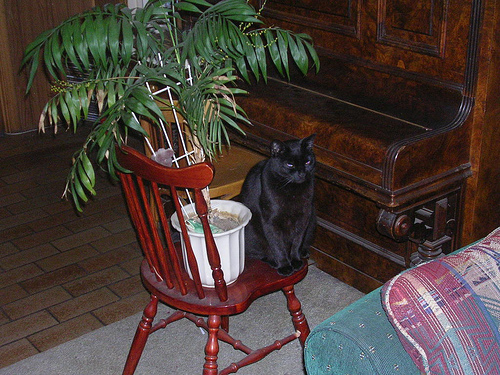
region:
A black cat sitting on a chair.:
[245, 138, 312, 273]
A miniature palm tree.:
[12, 0, 272, 145]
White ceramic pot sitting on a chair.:
[182, 195, 248, 288]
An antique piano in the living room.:
[315, 7, 499, 247]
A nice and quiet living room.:
[6, 4, 494, 374]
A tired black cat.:
[248, 134, 318, 276]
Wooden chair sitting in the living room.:
[115, 152, 300, 373]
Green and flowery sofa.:
[307, 239, 496, 373]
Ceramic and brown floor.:
[5, 180, 128, 336]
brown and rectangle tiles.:
[0, 220, 134, 317]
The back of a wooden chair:
[147, 172, 201, 287]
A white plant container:
[169, 197, 254, 287]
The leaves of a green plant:
[89, 9, 219, 92]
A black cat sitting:
[242, 133, 321, 273]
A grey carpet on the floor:
[43, 356, 123, 374]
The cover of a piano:
[321, 118, 396, 147]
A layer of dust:
[338, 228, 368, 246]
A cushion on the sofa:
[416, 287, 499, 344]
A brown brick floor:
[1, 248, 63, 329]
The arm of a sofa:
[329, 322, 386, 374]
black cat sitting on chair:
[235, 126, 320, 286]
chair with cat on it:
[114, 135, 321, 373]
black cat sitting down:
[246, 135, 323, 270]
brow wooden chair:
[93, 135, 323, 373]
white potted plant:
[170, 195, 251, 290]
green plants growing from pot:
[31, 9, 315, 227]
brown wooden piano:
[236, 0, 488, 279]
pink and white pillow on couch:
[382, 245, 499, 374]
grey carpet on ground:
[39, 323, 120, 374]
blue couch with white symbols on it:
[277, 293, 404, 374]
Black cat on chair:
[242, 138, 330, 271]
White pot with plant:
[162, 197, 256, 287]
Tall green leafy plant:
[20, 5, 308, 185]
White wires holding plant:
[127, 18, 222, 222]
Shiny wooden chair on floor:
[114, 135, 334, 373]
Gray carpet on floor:
[6, 248, 413, 369]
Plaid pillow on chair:
[382, 225, 499, 374]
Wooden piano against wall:
[147, 4, 495, 269]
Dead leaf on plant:
[93, 80, 108, 115]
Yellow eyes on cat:
[287, 158, 311, 168]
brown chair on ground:
[102, 153, 324, 374]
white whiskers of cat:
[278, 165, 336, 192]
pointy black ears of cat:
[270, 135, 319, 152]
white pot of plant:
[172, 198, 247, 290]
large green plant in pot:
[10, 4, 317, 249]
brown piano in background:
[265, 0, 480, 250]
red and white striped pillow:
[384, 242, 497, 374]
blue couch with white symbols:
[306, 276, 423, 373]